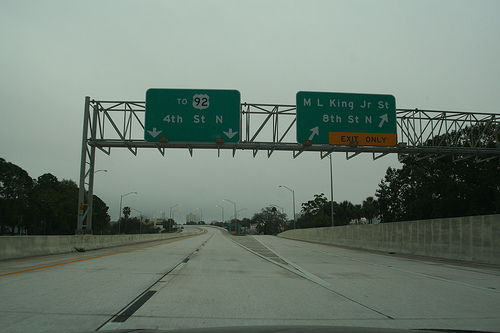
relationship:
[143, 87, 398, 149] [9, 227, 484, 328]
signs suspended over road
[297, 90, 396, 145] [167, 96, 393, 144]
green sign with printing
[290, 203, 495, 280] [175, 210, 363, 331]
barrier on highway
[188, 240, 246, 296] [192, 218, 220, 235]
highway and ramp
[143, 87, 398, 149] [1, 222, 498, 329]
signs above a highway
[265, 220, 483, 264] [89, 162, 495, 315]
wall near highway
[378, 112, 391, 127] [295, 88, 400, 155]
white arrow on green sign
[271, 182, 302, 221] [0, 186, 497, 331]
pole on highway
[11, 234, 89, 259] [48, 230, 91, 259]
barrier on road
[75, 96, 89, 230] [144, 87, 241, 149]
pole holding sign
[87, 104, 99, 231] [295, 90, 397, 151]
pole holding sign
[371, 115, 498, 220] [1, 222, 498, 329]
trees on side of highway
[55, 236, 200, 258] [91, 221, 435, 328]
line on highway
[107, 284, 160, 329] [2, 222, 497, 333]
line on highway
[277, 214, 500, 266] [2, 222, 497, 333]
wall along highway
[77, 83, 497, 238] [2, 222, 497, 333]
structure supports highway